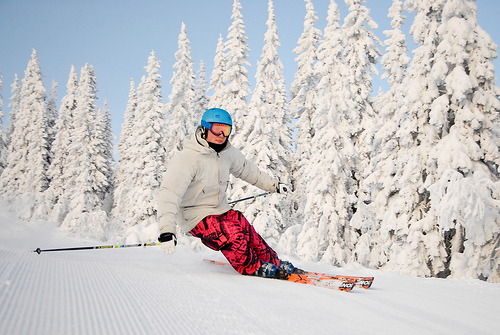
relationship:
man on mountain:
[152, 95, 303, 285] [2, 208, 498, 335]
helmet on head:
[201, 105, 235, 125] [198, 103, 230, 151]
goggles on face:
[207, 123, 234, 136] [207, 121, 232, 148]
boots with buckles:
[258, 254, 296, 279] [256, 260, 291, 272]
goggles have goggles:
[207, 123, 234, 136] [207, 123, 232, 136]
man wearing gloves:
[152, 95, 303, 285] [157, 230, 179, 256]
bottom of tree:
[4, 156, 50, 198] [7, 42, 67, 209]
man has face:
[152, 95, 303, 285] [207, 121, 232, 148]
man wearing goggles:
[152, 95, 303, 285] [207, 123, 234, 136]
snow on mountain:
[0, 217, 498, 333] [2, 208, 498, 335]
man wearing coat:
[152, 95, 303, 285] [156, 131, 278, 237]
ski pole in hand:
[29, 229, 176, 256] [157, 222, 181, 253]